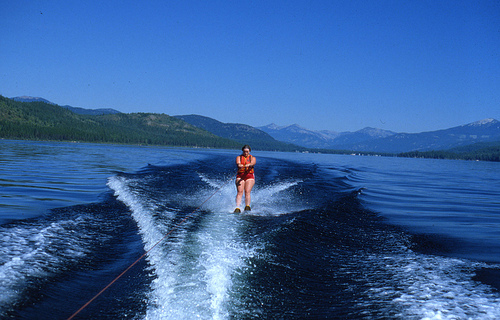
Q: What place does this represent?
A: It represents the lake.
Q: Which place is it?
A: It is a lake.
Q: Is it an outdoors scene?
A: Yes, it is outdoors.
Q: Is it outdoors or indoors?
A: It is outdoors.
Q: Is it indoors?
A: No, it is outdoors.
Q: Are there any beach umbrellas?
A: No, there are no beach umbrellas.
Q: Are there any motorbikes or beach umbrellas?
A: No, there are no beach umbrellas or motorbikes.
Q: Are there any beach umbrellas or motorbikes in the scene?
A: No, there are no beach umbrellas or motorbikes.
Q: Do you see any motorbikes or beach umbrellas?
A: No, there are no beach umbrellas or motorbikes.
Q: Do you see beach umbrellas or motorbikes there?
A: No, there are no beach umbrellas or motorbikes.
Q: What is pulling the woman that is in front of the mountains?
A: The rope is pulling the woman.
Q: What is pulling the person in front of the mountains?
A: The rope is pulling the woman.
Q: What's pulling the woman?
A: The rope is pulling the woman.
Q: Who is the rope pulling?
A: The rope is pulling the woman.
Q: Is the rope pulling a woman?
A: Yes, the rope is pulling a woman.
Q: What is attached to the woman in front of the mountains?
A: The rope is attached to the woman.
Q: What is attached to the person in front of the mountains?
A: The rope is attached to the woman.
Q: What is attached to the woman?
A: The rope is attached to the woman.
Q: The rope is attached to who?
A: The rope is attached to the woman.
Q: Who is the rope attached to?
A: The rope is attached to the woman.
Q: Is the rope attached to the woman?
A: Yes, the rope is attached to the woman.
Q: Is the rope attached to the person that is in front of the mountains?
A: Yes, the rope is attached to the woman.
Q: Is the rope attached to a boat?
A: No, the rope is attached to the woman.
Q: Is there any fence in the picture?
A: No, there are no fences.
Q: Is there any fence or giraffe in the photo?
A: No, there are no fences or giraffes.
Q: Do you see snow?
A: Yes, there is snow.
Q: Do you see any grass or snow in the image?
A: Yes, there is snow.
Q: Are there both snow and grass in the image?
A: No, there is snow but no grass.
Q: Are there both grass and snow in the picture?
A: No, there is snow but no grass.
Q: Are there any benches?
A: No, there are no benches.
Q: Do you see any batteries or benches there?
A: No, there are no benches or batteries.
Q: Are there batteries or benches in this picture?
A: No, there are no benches or batteries.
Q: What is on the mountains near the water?
A: The snow is on the mountains.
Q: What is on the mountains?
A: The snow is on the mountains.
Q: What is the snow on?
A: The snow is on the mountains.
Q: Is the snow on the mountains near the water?
A: Yes, the snow is on the mountains.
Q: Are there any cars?
A: No, there are no cars.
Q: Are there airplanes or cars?
A: No, there are no cars or airplanes.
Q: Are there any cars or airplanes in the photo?
A: No, there are no cars or airplanes.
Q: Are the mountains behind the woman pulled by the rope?
A: Yes, the mountains are behind the woman.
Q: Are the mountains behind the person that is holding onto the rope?
A: Yes, the mountains are behind the woman.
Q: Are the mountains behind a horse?
A: No, the mountains are behind the woman.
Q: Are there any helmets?
A: No, there are no helmets.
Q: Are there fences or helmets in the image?
A: No, there are no helmets or fences.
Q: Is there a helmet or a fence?
A: No, there are no helmets or fences.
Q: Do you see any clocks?
A: No, there are no clocks.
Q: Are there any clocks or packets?
A: No, there are no clocks or packets.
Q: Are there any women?
A: Yes, there is a woman.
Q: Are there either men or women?
A: Yes, there is a woman.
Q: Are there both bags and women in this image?
A: No, there is a woman but no bags.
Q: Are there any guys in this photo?
A: No, there are no guys.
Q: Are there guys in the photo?
A: No, there are no guys.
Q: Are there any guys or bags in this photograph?
A: No, there are no guys or bags.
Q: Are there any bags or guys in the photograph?
A: No, there are no guys or bags.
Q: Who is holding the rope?
A: The woman is holding the rope.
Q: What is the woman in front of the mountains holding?
A: The woman is holding the rope.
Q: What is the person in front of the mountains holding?
A: The woman is holding the rope.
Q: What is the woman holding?
A: The woman is holding the rope.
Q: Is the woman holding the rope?
A: Yes, the woman is holding the rope.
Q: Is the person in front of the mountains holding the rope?
A: Yes, the woman is holding the rope.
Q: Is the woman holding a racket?
A: No, the woman is holding the rope.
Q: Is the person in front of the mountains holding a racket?
A: No, the woman is holding the rope.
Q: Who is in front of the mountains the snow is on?
A: The woman is in front of the mountains.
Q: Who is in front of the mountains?
A: The woman is in front of the mountains.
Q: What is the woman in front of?
A: The woman is in front of the mountains.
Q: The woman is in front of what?
A: The woman is in front of the mountains.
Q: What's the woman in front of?
A: The woman is in front of the mountains.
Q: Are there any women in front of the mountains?
A: Yes, there is a woman in front of the mountains.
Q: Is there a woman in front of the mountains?
A: Yes, there is a woman in front of the mountains.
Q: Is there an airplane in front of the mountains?
A: No, there is a woman in front of the mountains.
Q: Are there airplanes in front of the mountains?
A: No, there is a woman in front of the mountains.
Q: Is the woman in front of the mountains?
A: Yes, the woman is in front of the mountains.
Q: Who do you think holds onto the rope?
A: The woman holds onto the rope.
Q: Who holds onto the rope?
A: The woman holds onto the rope.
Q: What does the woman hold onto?
A: The woman holds onto the rope.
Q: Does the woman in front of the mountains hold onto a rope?
A: Yes, the woman holds onto a rope.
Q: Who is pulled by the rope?
A: The woman is pulled by the rope.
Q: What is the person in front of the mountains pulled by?
A: The woman is pulled by the rope.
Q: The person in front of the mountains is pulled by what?
A: The woman is pulled by the rope.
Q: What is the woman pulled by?
A: The woman is pulled by the rope.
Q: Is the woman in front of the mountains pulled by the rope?
A: Yes, the woman is pulled by the rope.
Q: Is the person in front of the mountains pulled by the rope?
A: Yes, the woman is pulled by the rope.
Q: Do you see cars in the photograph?
A: No, there are no cars.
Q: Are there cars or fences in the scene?
A: No, there are no cars or fences.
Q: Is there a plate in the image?
A: No, there are no plates.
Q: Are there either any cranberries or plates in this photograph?
A: No, there are no plates or cranberries.